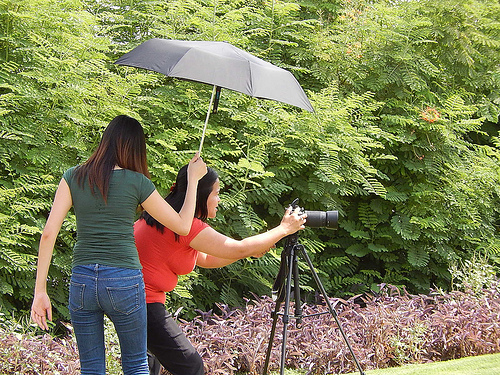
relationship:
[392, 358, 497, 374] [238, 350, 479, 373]
grass on ground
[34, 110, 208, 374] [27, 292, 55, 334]
ladies has hand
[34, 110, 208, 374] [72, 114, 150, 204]
ladies has hair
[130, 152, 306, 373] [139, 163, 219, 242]
woman has hair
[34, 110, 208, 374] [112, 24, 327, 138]
ladies has umbrella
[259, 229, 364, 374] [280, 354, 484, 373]
stand on grass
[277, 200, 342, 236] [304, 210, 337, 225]
camera has lens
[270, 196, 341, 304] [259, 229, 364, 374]
camera on stand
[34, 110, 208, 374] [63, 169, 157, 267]
ladies wearing green shirt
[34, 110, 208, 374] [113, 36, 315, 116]
ladies holding umbrella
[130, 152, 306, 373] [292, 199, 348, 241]
woman holding camera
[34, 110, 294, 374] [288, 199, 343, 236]
ladies looking at camera